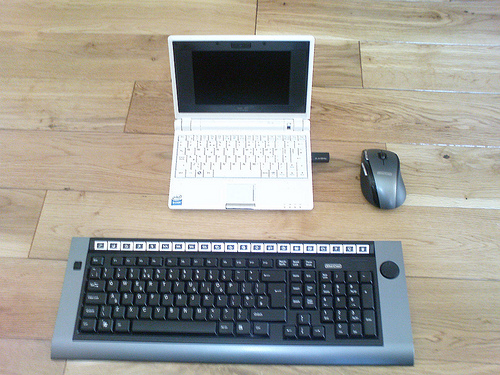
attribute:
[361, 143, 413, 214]
mouse — gray, black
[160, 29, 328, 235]
laptop — white, off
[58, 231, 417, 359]
keyboard — black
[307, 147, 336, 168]
usb — black